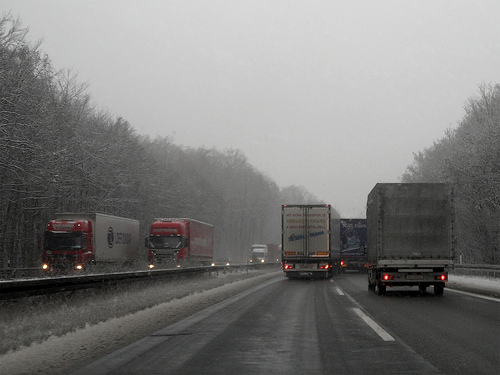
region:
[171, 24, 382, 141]
The sky is overcast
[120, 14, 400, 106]
The sky is gray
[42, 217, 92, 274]
The truck is red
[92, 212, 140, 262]
The trailer is white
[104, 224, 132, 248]
The trailer has writing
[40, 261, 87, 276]
The headlights are on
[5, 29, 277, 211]
Snow covered trees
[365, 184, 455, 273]
The truck looks dirty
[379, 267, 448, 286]
The lights are red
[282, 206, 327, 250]
The back of the truck has writing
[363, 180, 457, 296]
the back of a white truck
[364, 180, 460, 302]
a dirty white truck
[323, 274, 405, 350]
white highway lines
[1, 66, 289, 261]
snow covered trees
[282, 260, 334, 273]
the break lights of a truck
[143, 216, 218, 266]
a big red truck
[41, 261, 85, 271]
two headlights that are on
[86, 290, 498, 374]
a section of black road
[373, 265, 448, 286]
the bumper of a truck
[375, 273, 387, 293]
a black back tire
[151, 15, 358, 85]
this is the sky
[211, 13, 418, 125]
the sky is full of clouds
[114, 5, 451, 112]
the clouds are white in color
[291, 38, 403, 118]
the sky is dull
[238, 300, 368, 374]
this is the road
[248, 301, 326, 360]
the road has some snow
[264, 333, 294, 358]
the snow is white in color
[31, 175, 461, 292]
these are several trucks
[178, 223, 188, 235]
the truck is red in color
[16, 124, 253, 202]
these are several trees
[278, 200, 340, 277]
this is a trailer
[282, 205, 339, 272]
the trailer is moving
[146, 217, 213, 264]
the trailer is red in color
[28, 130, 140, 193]
the trees are beside the road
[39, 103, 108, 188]
the trees are white in color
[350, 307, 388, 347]
the strip is white in color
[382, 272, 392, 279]
the light is red in color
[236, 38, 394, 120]
the sky is white in color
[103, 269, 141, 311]
this is a barrier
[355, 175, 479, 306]
this is a truck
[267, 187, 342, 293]
this is a semi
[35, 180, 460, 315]
many trucks on an interstate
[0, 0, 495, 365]
it is a grey and snowy day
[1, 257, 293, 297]
the guard rail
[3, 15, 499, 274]
the trees line the road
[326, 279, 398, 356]
the lines are on the road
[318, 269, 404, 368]
the lines are painted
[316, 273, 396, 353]
the lines are white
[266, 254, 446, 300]
the brake lights are red